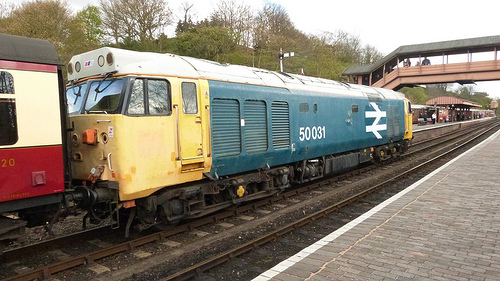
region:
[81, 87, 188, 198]
A train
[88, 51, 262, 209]
A train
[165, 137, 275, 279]
A train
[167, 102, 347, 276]
A train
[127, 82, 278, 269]
A train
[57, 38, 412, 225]
Yellow and blue train engine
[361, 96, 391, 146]
a train company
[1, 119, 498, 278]
train tracks near station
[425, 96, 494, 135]
passengers waiting at a train depot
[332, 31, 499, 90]
a pedestrian bridge over tracks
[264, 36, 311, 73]
overhead lights seen behind engine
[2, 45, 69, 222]
rear of a red and white train car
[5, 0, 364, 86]
tree tops along the tracks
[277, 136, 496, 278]
a brick walkway beside tracks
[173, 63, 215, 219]
door and steps to enter train car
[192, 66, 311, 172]
A train is visible.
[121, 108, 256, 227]
A train is visible.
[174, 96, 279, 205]
A train is visible.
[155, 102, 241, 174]
A train is visible.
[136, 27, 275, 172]
A train is visible.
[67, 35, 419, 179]
blue and yellow train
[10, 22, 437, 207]
train pulling in to the station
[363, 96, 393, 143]
white lines on blue background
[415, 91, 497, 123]
people waiting on the train platform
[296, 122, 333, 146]
white numbers on the train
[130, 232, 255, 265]
railroad tracks at the station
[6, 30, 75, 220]
red and white caboose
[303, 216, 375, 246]
white stripe at the edge of the platform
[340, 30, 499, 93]
pedestrian overpass at the station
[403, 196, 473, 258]
empty brick paved platform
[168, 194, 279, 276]
The railroad is visible.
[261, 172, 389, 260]
The railroad is visible.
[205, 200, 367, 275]
The railroad is visible.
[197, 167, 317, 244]
The railroad is visible.